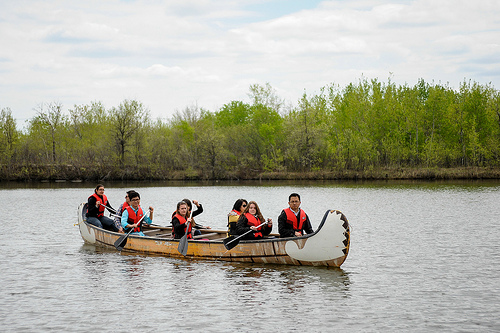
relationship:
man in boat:
[276, 186, 316, 243] [64, 200, 363, 276]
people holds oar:
[236, 201, 273, 240] [221, 216, 275, 263]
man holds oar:
[117, 189, 154, 236] [111, 207, 148, 249]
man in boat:
[278, 193, 315, 239] [72, 194, 352, 271]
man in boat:
[278, 193, 315, 239] [77, 203, 349, 261]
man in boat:
[85, 184, 117, 231] [78, 201, 351, 267]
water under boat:
[7, 183, 494, 331] [78, 201, 351, 267]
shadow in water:
[41, 237, 355, 307] [7, 183, 494, 331]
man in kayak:
[278, 193, 315, 239] [72, 197, 349, 269]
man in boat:
[278, 193, 315, 239] [78, 201, 351, 267]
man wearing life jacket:
[278, 193, 315, 239] [280, 207, 306, 237]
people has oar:
[236, 201, 273, 240] [220, 222, 266, 252]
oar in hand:
[220, 222, 266, 252] [248, 222, 258, 232]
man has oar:
[83, 183, 112, 223] [96, 200, 118, 214]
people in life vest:
[171, 200, 204, 239] [88, 192, 108, 219]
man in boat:
[278, 193, 315, 239] [67, 189, 382, 266]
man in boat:
[85, 184, 117, 231] [76, 204, 360, 279]